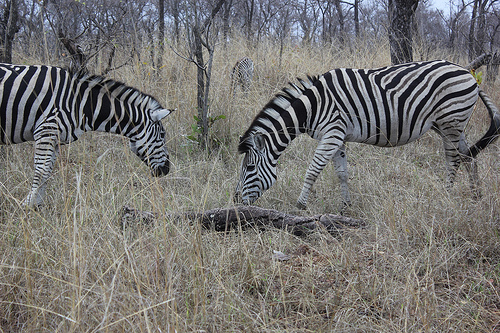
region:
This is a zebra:
[213, 42, 497, 219]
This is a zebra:
[0, 60, 187, 217]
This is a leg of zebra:
[326, 127, 362, 221]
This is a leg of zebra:
[293, 117, 340, 208]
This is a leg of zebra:
[428, 104, 467, 194]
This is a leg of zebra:
[458, 118, 489, 210]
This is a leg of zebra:
[19, 122, 55, 237]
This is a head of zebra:
[132, 96, 187, 183]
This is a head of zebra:
[231, 117, 285, 214]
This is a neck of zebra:
[267, 76, 308, 160]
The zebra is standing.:
[220, 78, 498, 195]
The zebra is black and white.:
[230, 55, 497, 227]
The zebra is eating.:
[220, 49, 485, 239]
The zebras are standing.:
[2, 34, 498, 233]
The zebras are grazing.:
[2, 46, 498, 251]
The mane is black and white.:
[220, 63, 315, 143]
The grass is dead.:
[5, 141, 498, 324]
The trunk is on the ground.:
[113, 192, 383, 262]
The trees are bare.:
[7, 2, 498, 90]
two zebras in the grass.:
[5, 53, 496, 298]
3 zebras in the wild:
[10, 47, 477, 213]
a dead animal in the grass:
[95, 177, 377, 246]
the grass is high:
[233, 123, 436, 316]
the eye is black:
[238, 157, 262, 186]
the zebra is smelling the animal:
[197, 122, 287, 204]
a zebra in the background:
[193, 27, 268, 102]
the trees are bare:
[148, 0, 228, 125]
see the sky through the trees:
[208, 0, 374, 39]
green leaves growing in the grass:
[167, 89, 230, 159]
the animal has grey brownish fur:
[95, 193, 376, 265]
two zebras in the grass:
[3, 40, 495, 275]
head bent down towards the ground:
[194, 98, 296, 232]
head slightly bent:
[123, 97, 187, 184]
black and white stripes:
[344, 71, 429, 137]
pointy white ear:
[144, 98, 183, 126]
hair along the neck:
[62, 61, 161, 113]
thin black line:
[32, 144, 57, 153]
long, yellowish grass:
[12, 145, 499, 332]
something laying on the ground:
[119, 201, 371, 244]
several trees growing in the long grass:
[1, 0, 499, 67]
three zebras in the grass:
[21, 40, 483, 260]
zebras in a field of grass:
[18, 42, 446, 241]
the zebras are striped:
[3, 27, 498, 297]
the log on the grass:
[109, 195, 389, 255]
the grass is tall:
[31, 193, 225, 307]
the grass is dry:
[48, 222, 217, 307]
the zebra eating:
[206, 87, 498, 224]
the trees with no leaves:
[28, 6, 496, 47]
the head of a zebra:
[107, 91, 184, 177]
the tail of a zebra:
[217, 54, 245, 98]